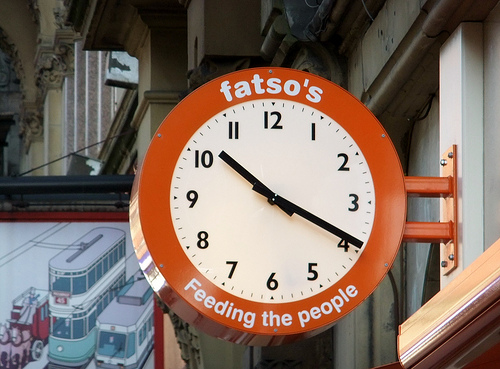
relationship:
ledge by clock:
[388, 242, 497, 365] [119, 60, 478, 327]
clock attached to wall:
[119, 50, 383, 351] [431, 84, 486, 250]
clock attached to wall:
[119, 50, 383, 351] [416, 85, 466, 259]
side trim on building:
[394, 263, 493, 338] [283, 26, 471, 279]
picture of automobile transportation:
[10, 185, 172, 348] [4, 223, 157, 363]